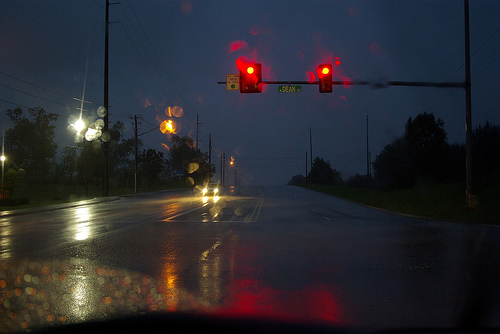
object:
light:
[61, 194, 105, 243]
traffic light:
[316, 48, 334, 93]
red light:
[320, 64, 334, 76]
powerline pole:
[99, 0, 114, 195]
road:
[0, 184, 500, 333]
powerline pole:
[130, 113, 142, 194]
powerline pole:
[364, 115, 375, 195]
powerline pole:
[307, 126, 315, 181]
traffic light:
[235, 51, 268, 94]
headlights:
[209, 184, 222, 194]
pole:
[462, 0, 474, 212]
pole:
[309, 126, 314, 183]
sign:
[223, 73, 243, 91]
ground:
[0, 183, 500, 333]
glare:
[69, 115, 90, 133]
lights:
[70, 120, 83, 132]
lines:
[254, 200, 264, 225]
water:
[0, 258, 208, 318]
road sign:
[276, 82, 303, 95]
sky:
[2, 0, 500, 185]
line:
[322, 216, 338, 226]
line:
[311, 208, 318, 214]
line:
[301, 199, 309, 209]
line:
[288, 191, 291, 197]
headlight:
[202, 188, 208, 194]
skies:
[111, 14, 170, 102]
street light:
[160, 119, 182, 134]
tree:
[4, 103, 62, 178]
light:
[241, 65, 257, 77]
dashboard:
[0, 0, 500, 329]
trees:
[373, 112, 458, 200]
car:
[199, 180, 229, 196]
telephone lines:
[2, 71, 104, 105]